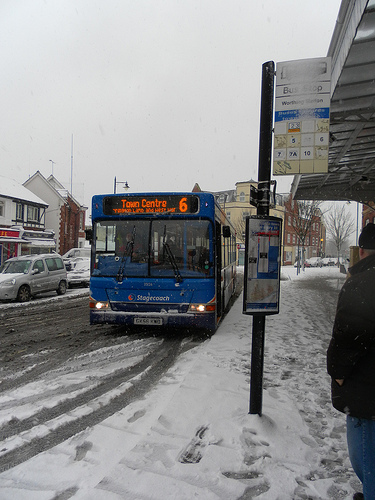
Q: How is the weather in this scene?
A: It is overcast.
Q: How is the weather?
A: It is overcast.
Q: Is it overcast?
A: Yes, it is overcast.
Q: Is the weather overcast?
A: Yes, it is overcast.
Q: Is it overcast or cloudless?
A: It is overcast.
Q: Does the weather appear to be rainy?
A: No, it is overcast.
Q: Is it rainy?
A: No, it is overcast.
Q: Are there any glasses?
A: No, there are no glasses.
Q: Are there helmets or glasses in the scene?
A: No, there are no glasses or helmets.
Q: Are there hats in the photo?
A: Yes, there is a hat.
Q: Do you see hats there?
A: Yes, there is a hat.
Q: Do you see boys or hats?
A: Yes, there is a hat.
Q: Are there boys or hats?
A: Yes, there is a hat.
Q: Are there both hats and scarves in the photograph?
A: No, there is a hat but no scarves.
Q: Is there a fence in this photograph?
A: No, there are no fences.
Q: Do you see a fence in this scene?
A: No, there are no fences.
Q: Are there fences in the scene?
A: No, there are no fences.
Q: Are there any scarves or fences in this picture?
A: No, there are no fences or scarves.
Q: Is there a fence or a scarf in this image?
A: No, there are no fences or scarves.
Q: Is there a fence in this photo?
A: No, there are no fences.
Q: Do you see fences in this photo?
A: No, there are no fences.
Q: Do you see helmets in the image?
A: No, there are no helmets.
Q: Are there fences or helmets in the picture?
A: No, there are no helmets or fences.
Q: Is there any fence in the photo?
A: No, there are no fences.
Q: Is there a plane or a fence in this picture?
A: No, there are no fences or airplanes.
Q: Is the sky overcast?
A: Yes, the sky is overcast.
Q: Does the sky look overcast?
A: Yes, the sky is overcast.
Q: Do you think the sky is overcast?
A: Yes, the sky is overcast.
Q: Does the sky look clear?
A: No, the sky is overcast.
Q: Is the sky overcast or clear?
A: The sky is overcast.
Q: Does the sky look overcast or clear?
A: The sky is overcast.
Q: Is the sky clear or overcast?
A: The sky is overcast.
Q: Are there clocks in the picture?
A: No, there are no clocks.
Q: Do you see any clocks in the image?
A: No, there are no clocks.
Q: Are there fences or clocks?
A: No, there are no clocks or fences.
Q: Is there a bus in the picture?
A: Yes, there is a bus.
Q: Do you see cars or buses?
A: Yes, there is a bus.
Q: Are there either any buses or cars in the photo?
A: Yes, there is a bus.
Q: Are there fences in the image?
A: No, there are no fences.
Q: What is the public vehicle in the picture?
A: The vehicle is a bus.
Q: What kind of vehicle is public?
A: The vehicle is a bus.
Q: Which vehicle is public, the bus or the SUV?
A: The bus is public.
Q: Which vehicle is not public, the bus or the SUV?
A: The SUV is not public.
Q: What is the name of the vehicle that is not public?
A: The vehicle is a SUV.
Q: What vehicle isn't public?
A: The vehicle is a SUV.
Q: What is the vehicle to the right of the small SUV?
A: The vehicle is a bus.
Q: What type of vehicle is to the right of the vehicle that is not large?
A: The vehicle is a bus.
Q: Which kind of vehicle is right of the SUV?
A: The vehicle is a bus.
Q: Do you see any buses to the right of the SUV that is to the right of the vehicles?
A: Yes, there is a bus to the right of the SUV.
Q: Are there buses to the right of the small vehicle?
A: Yes, there is a bus to the right of the SUV.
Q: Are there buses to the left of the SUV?
A: No, the bus is to the right of the SUV.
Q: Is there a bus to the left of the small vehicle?
A: No, the bus is to the right of the SUV.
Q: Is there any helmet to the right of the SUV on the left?
A: No, there is a bus to the right of the SUV.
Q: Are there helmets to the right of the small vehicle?
A: No, there is a bus to the right of the SUV.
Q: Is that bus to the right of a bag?
A: No, the bus is to the right of the SUV.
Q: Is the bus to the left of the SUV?
A: No, the bus is to the right of the SUV.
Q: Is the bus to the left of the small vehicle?
A: No, the bus is to the right of the SUV.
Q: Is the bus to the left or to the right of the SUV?
A: The bus is to the right of the SUV.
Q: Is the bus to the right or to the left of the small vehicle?
A: The bus is to the right of the SUV.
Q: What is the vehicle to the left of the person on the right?
A: The vehicle is a bus.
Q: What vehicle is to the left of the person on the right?
A: The vehicle is a bus.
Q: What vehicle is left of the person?
A: The vehicle is a bus.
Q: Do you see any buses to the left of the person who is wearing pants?
A: Yes, there is a bus to the left of the person.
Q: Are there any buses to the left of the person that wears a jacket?
A: Yes, there is a bus to the left of the person.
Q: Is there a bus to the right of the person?
A: No, the bus is to the left of the person.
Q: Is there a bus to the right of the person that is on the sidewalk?
A: No, the bus is to the left of the person.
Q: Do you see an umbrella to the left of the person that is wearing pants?
A: No, there is a bus to the left of the person.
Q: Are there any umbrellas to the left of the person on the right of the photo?
A: No, there is a bus to the left of the person.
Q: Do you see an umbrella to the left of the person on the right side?
A: No, there is a bus to the left of the person.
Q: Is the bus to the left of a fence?
A: No, the bus is to the left of the person.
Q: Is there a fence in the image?
A: No, there are no fences.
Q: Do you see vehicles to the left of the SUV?
A: Yes, there are vehicles to the left of the SUV.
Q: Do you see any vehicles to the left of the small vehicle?
A: Yes, there are vehicles to the left of the SUV.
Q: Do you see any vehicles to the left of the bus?
A: Yes, there are vehicles to the left of the bus.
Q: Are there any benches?
A: No, there are no benches.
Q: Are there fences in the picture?
A: No, there are no fences.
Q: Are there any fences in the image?
A: No, there are no fences.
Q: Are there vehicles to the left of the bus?
A: Yes, there are vehicles to the left of the bus.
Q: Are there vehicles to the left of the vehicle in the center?
A: Yes, there are vehicles to the left of the bus.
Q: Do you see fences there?
A: No, there are no fences.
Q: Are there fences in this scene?
A: No, there are no fences.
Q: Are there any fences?
A: No, there are no fences.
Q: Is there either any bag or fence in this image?
A: No, there are no fences or bags.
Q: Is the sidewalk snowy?
A: Yes, the sidewalk is snowy.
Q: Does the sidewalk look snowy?
A: Yes, the sidewalk is snowy.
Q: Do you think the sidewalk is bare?
A: No, the sidewalk is snowy.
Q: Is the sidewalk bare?
A: No, the sidewalk is snowy.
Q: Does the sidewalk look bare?
A: No, the sidewalk is snowy.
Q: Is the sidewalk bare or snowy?
A: The sidewalk is snowy.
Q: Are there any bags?
A: No, there are no bags.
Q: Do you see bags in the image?
A: No, there are no bags.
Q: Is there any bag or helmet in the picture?
A: No, there are no bags or helmets.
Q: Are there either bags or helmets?
A: No, there are no bags or helmets.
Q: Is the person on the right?
A: Yes, the person is on the right of the image.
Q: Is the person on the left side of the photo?
A: No, the person is on the right of the image.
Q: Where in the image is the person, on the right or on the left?
A: The person is on the right of the image.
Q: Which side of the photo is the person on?
A: The person is on the right of the image.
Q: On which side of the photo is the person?
A: The person is on the right of the image.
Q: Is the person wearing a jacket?
A: Yes, the person is wearing a jacket.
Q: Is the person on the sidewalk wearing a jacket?
A: Yes, the person is wearing a jacket.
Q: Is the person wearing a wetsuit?
A: No, the person is wearing a jacket.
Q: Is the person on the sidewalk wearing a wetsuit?
A: No, the person is wearing a jacket.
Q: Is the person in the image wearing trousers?
A: Yes, the person is wearing trousers.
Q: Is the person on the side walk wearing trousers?
A: Yes, the person is wearing trousers.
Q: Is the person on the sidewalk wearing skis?
A: No, the person is wearing trousers.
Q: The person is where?
A: The person is on the sidewalk.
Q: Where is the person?
A: The person is on the sidewalk.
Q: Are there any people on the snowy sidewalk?
A: Yes, there is a person on the sidewalk.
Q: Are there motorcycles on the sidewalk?
A: No, there is a person on the sidewalk.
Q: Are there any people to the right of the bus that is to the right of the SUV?
A: Yes, there is a person to the right of the bus.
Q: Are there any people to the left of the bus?
A: No, the person is to the right of the bus.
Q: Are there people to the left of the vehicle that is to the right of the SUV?
A: No, the person is to the right of the bus.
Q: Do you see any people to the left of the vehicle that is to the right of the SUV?
A: No, the person is to the right of the bus.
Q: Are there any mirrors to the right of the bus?
A: No, there is a person to the right of the bus.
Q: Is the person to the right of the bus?
A: Yes, the person is to the right of the bus.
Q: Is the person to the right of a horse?
A: No, the person is to the right of the bus.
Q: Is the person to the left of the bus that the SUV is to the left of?
A: No, the person is to the right of the bus.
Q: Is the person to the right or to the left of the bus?
A: The person is to the right of the bus.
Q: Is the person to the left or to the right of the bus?
A: The person is to the right of the bus.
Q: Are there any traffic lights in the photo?
A: No, there are no traffic lights.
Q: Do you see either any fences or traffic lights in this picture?
A: No, there are no traffic lights or fences.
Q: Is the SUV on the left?
A: Yes, the SUV is on the left of the image.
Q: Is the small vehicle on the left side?
A: Yes, the SUV is on the left of the image.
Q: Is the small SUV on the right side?
A: No, the SUV is on the left of the image.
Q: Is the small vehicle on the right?
A: No, the SUV is on the left of the image.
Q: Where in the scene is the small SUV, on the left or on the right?
A: The SUV is on the left of the image.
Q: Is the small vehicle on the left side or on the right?
A: The SUV is on the left of the image.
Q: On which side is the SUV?
A: The SUV is on the left of the image.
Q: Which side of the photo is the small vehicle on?
A: The SUV is on the left of the image.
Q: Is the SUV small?
A: Yes, the SUV is small.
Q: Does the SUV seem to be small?
A: Yes, the SUV is small.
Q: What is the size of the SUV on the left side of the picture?
A: The SUV is small.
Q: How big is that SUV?
A: The SUV is small.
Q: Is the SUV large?
A: No, the SUV is small.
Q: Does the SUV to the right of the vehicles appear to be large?
A: No, the SUV is small.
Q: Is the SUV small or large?
A: The SUV is small.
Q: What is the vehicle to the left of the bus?
A: The vehicle is a SUV.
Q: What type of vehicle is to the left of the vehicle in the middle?
A: The vehicle is a SUV.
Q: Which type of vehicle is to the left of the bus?
A: The vehicle is a SUV.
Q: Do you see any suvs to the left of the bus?
A: Yes, there is a SUV to the left of the bus.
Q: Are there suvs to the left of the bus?
A: Yes, there is a SUV to the left of the bus.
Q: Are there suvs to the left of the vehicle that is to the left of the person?
A: Yes, there is a SUV to the left of the bus.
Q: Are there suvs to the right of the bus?
A: No, the SUV is to the left of the bus.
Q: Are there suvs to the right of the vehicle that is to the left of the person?
A: No, the SUV is to the left of the bus.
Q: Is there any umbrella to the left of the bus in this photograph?
A: No, there is a SUV to the left of the bus.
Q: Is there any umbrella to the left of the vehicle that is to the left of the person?
A: No, there is a SUV to the left of the bus.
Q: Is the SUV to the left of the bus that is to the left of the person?
A: Yes, the SUV is to the left of the bus.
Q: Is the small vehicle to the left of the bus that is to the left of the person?
A: Yes, the SUV is to the left of the bus.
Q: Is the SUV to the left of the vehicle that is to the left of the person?
A: Yes, the SUV is to the left of the bus.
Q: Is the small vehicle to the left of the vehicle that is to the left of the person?
A: Yes, the SUV is to the left of the bus.